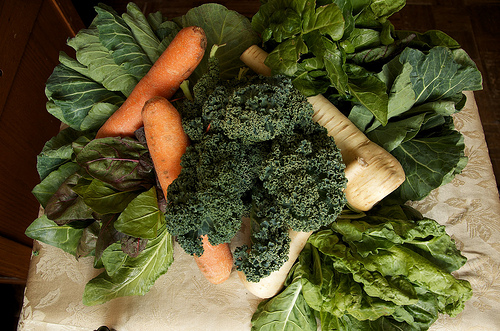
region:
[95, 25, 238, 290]
the carrots are orange.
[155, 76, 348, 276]
the broccoli is green.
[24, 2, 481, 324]
the lettuce is green.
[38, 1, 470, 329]
vegetables on a table.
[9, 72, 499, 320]
the table is tan.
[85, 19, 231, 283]
two carrots on the table.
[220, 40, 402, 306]
the okra is white.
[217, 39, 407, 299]
two pieces of okra on the table.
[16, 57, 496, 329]
floral pattern on the table.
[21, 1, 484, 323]
the vegetables are fresh.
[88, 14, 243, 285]
two carrots are visible.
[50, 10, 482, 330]
the lettuce is green.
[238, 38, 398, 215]
the vegetable is white.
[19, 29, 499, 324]
the table is tan.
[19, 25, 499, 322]
the table is patterned.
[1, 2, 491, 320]
the background is black.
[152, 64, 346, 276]
the broccoli is bushy.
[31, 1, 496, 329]
vegetables over a table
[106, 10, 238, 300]
two unpeeled carrots on top of leaves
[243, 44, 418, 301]
two white radish under green leaves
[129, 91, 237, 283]
carrots is big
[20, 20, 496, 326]
table is small and has a table coat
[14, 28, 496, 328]
table coat is tan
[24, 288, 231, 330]
table cloths has flowered designs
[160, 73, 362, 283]
leaves are dark green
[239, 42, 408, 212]
vegetable is long and white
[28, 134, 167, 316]
leaves are green and red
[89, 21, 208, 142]
an orange carrot on the table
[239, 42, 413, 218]
a white turnip on the table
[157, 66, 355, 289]
green kale on the table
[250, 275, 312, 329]
a leaf of green lettuce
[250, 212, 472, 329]
a head of lettuce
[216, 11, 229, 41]
a vein on the leaf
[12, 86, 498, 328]
a white tablecloth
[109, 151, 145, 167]
a purple vein on the leaf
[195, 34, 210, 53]
a brown spot on the carrot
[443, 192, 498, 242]
a pattern on the tablecloth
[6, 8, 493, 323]
A bunch of fresh vegetables.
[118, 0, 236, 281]
Two carrots in the veggies.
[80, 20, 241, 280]
The carrots are orange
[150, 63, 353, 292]
A bunch of green kale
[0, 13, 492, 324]
Photo taken during the day.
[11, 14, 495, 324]
Nobody shown in the picture.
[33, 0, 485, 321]
Veggies are orange, green and white.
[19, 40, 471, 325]
White napkin with veggies on it.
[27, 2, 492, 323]
There are no fruits.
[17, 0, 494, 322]
Vegetarian meal